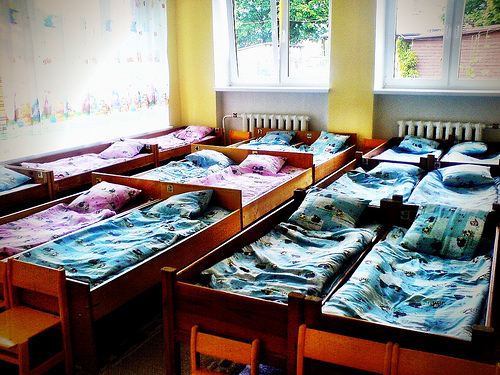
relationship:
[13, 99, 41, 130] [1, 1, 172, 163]
drawing on wall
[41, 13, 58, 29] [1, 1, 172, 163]
drawing on wall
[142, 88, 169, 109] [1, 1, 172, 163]
drawing on wall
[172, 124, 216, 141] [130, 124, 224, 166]
pillow on bed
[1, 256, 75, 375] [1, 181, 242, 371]
chair next to bed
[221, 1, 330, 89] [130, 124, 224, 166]
window above bed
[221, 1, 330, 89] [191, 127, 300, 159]
window above bed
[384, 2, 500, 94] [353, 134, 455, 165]
window above bed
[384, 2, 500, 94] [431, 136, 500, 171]
window above bed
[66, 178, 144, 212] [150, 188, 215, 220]
pillow next to pillow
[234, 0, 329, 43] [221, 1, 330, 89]
trees are outside window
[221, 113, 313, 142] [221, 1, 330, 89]
radiator under window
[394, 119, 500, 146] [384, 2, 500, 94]
radiator under window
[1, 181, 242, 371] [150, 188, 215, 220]
bed with pillow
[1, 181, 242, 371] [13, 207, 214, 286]
bed with sheet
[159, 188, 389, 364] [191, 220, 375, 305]
bed with sheet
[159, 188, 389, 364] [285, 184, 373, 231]
bed with pillow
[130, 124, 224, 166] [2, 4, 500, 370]
bed in room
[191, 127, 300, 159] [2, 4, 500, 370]
bed in room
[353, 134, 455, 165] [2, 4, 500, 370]
bed in room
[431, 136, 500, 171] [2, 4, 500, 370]
bed in room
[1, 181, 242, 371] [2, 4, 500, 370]
bed in room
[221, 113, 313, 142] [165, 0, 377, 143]
radiator on wall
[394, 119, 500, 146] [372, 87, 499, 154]
radiator on wall